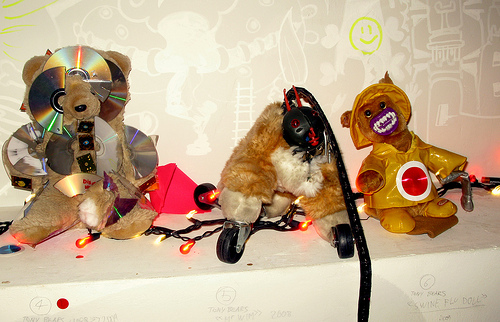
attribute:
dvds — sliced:
[27, 63, 67, 161]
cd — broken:
[51, 54, 117, 92]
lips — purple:
[371, 118, 404, 135]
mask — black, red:
[291, 114, 315, 147]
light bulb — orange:
[192, 183, 221, 205]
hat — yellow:
[361, 91, 416, 117]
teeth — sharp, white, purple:
[377, 121, 394, 128]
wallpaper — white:
[56, 1, 491, 115]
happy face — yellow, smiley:
[347, 8, 391, 64]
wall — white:
[7, 11, 499, 178]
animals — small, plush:
[214, 93, 470, 247]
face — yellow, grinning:
[358, 108, 406, 141]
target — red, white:
[394, 168, 445, 200]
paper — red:
[150, 166, 211, 220]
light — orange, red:
[295, 213, 324, 236]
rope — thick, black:
[342, 199, 373, 317]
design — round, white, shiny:
[382, 162, 441, 202]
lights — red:
[73, 225, 328, 250]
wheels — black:
[221, 225, 357, 266]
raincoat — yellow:
[377, 155, 466, 208]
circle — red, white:
[393, 163, 435, 201]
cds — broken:
[12, 61, 78, 176]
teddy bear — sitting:
[9, 52, 174, 255]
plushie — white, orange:
[225, 101, 346, 241]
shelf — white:
[22, 257, 493, 308]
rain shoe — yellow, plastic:
[387, 215, 415, 234]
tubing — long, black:
[309, 101, 369, 265]